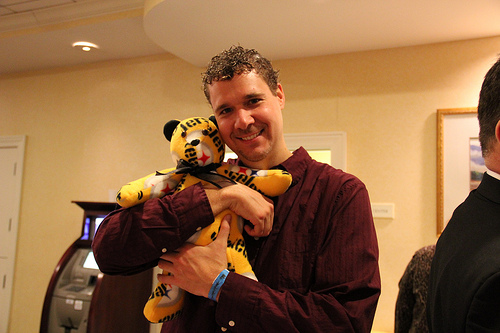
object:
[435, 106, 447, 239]
brown wood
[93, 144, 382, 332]
maroon shirt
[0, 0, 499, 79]
ceiling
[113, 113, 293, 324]
stuffed animal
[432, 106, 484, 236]
picture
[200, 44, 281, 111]
hair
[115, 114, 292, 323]
animal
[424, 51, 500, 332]
man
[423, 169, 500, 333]
jacket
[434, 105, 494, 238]
frame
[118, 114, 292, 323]
teddy bear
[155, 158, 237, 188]
black ribbon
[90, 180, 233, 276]
right arm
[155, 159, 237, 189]
lace bow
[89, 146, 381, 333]
shirt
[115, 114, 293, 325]
bear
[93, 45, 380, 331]
man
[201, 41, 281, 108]
curly hair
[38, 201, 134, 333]
atm machine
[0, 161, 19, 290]
silver hinges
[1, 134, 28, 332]
door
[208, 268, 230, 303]
blue band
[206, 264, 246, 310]
man's wrist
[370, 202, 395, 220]
thermostat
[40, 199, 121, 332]
teller machine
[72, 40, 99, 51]
light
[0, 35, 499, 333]
wall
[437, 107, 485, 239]
art print